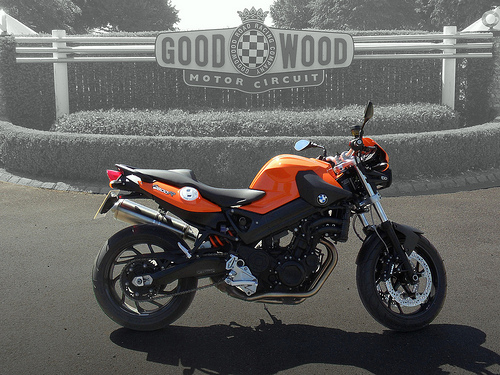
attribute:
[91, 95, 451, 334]
bike — in color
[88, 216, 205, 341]
wheel — rear 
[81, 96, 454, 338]
motorcycle — black, orange